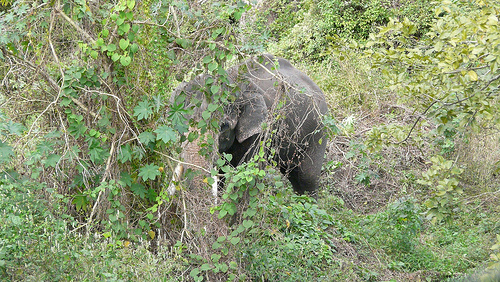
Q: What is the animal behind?
A: A tree.